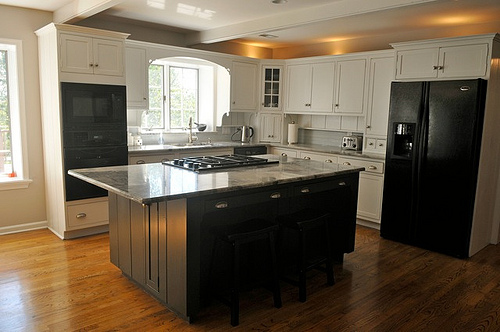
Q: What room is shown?
A: It is a kitchen.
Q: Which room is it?
A: It is a kitchen.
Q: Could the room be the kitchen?
A: Yes, it is the kitchen.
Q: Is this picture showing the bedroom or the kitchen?
A: It is showing the kitchen.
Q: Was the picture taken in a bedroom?
A: No, the picture was taken in a kitchen.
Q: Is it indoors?
A: Yes, it is indoors.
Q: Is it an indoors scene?
A: Yes, it is indoors.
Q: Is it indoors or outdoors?
A: It is indoors.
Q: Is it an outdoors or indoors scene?
A: It is indoors.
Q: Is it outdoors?
A: No, it is indoors.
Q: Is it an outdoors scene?
A: No, it is indoors.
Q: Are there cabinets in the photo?
A: Yes, there is a cabinet.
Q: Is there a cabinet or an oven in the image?
A: Yes, there is a cabinet.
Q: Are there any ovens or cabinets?
A: Yes, there is a cabinet.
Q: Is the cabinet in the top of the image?
A: Yes, the cabinet is in the top of the image.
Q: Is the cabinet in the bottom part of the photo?
A: No, the cabinet is in the top of the image.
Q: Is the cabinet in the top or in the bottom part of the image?
A: The cabinet is in the top of the image.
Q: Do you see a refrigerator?
A: Yes, there is a refrigerator.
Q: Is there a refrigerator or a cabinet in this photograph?
A: Yes, there is a refrigerator.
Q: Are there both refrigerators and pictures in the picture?
A: No, there is a refrigerator but no pictures.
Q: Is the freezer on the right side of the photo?
A: Yes, the freezer is on the right of the image.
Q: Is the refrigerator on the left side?
A: No, the refrigerator is on the right of the image.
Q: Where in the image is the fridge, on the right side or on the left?
A: The fridge is on the right of the image.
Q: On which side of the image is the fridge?
A: The fridge is on the right of the image.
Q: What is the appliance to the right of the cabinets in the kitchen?
A: The appliance is a refrigerator.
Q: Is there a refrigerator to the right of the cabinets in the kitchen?
A: Yes, there is a refrigerator to the right of the cabinets.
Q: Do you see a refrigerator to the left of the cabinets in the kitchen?
A: No, the refrigerator is to the right of the cabinets.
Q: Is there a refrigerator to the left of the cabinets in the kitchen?
A: No, the refrigerator is to the right of the cabinets.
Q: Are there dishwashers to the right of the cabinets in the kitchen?
A: No, there is a refrigerator to the right of the cabinets.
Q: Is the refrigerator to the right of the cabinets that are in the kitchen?
A: Yes, the refrigerator is to the right of the cabinets.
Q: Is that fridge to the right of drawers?
A: No, the fridge is to the right of the cabinets.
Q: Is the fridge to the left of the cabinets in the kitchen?
A: No, the fridge is to the right of the cabinets.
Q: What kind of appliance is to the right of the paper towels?
A: The appliance is a refrigerator.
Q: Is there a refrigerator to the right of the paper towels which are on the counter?
A: Yes, there is a refrigerator to the right of the paper towels.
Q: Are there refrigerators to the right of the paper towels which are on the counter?
A: Yes, there is a refrigerator to the right of the paper towels.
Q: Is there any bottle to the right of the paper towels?
A: No, there is a refrigerator to the right of the paper towels.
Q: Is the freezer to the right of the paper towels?
A: Yes, the freezer is to the right of the paper towels.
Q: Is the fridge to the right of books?
A: No, the fridge is to the right of the paper towels.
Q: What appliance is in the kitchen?
A: The appliance is a refrigerator.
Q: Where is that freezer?
A: The freezer is in the kitchen.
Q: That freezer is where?
A: The freezer is in the kitchen.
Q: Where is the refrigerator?
A: The freezer is in the kitchen.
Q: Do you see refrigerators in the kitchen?
A: Yes, there is a refrigerator in the kitchen.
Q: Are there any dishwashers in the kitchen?
A: No, there is a refrigerator in the kitchen.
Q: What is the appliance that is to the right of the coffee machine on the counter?
A: The appliance is a refrigerator.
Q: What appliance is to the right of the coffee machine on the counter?
A: The appliance is a refrigerator.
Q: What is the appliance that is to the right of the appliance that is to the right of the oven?
A: The appliance is a refrigerator.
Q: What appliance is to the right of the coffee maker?
A: The appliance is a refrigerator.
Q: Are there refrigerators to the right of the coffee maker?
A: Yes, there is a refrigerator to the right of the coffee maker.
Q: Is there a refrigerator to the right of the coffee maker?
A: Yes, there is a refrigerator to the right of the coffee maker.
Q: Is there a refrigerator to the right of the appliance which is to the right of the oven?
A: Yes, there is a refrigerator to the right of the coffee maker.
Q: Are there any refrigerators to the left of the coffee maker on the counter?
A: No, the refrigerator is to the right of the coffee machine.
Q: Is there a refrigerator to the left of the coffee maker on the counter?
A: No, the refrigerator is to the right of the coffee machine.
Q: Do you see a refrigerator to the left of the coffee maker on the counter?
A: No, the refrigerator is to the right of the coffee machine.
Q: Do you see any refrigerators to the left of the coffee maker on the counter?
A: No, the refrigerator is to the right of the coffee machine.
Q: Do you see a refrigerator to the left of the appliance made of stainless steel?
A: No, the refrigerator is to the right of the coffee machine.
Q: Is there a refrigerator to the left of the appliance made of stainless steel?
A: No, the refrigerator is to the right of the coffee machine.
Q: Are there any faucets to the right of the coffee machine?
A: No, there is a refrigerator to the right of the coffee machine.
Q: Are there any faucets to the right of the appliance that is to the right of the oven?
A: No, there is a refrigerator to the right of the coffee machine.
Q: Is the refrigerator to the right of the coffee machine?
A: Yes, the refrigerator is to the right of the coffee machine.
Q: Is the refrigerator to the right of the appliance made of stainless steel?
A: Yes, the refrigerator is to the right of the coffee machine.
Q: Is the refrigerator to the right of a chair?
A: No, the refrigerator is to the right of the coffee machine.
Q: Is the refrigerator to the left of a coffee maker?
A: No, the refrigerator is to the right of a coffee maker.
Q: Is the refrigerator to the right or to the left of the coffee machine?
A: The refrigerator is to the right of the coffee machine.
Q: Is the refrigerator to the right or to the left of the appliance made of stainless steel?
A: The refrigerator is to the right of the coffee machine.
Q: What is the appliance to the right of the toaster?
A: The appliance is a refrigerator.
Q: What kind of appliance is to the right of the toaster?
A: The appliance is a refrigerator.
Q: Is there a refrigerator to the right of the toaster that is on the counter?
A: Yes, there is a refrigerator to the right of the toaster.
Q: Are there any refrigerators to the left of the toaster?
A: No, the refrigerator is to the right of the toaster.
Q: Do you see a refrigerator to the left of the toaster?
A: No, the refrigerator is to the right of the toaster.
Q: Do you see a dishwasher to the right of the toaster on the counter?
A: No, there is a refrigerator to the right of the toaster.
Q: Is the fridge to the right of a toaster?
A: Yes, the fridge is to the right of a toaster.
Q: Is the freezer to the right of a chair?
A: No, the freezer is to the right of a toaster.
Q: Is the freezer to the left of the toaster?
A: No, the freezer is to the right of the toaster.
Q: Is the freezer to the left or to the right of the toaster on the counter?
A: The freezer is to the right of the toaster.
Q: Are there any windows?
A: Yes, there is a window.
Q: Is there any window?
A: Yes, there is a window.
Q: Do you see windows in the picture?
A: Yes, there is a window.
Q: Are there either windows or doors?
A: Yes, there is a window.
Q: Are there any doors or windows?
A: Yes, there is a window.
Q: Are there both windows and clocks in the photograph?
A: No, there is a window but no clocks.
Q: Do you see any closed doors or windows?
A: Yes, there is a closed window.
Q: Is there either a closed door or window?
A: Yes, there is a closed window.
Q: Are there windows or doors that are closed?
A: Yes, the window is closed.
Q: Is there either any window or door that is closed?
A: Yes, the window is closed.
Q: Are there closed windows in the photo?
A: Yes, there is a closed window.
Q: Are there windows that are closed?
A: Yes, there is a window that is closed.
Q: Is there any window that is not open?
A: Yes, there is an closed window.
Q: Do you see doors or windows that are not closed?
A: No, there is a window but it is closed.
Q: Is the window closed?
A: Yes, the window is closed.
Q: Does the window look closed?
A: Yes, the window is closed.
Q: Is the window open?
A: No, the window is closed.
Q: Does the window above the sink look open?
A: No, the window is closed.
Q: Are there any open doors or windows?
A: No, there is a window but it is closed.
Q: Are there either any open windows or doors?
A: No, there is a window but it is closed.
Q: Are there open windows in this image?
A: No, there is a window but it is closed.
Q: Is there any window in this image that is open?
A: No, there is a window but it is closed.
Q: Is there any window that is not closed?
A: No, there is a window but it is closed.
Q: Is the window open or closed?
A: The window is closed.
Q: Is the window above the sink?
A: Yes, the window is above the sink.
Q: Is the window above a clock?
A: No, the window is above the sink.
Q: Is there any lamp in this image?
A: No, there are no lamps.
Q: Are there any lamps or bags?
A: No, there are no lamps or bags.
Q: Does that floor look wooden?
A: Yes, the floor is wooden.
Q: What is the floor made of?
A: The floor is made of wood.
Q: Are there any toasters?
A: Yes, there is a toaster.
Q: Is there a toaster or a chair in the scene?
A: Yes, there is a toaster.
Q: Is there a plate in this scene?
A: No, there are no plates.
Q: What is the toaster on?
A: The toaster is on the counter.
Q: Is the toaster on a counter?
A: Yes, the toaster is on a counter.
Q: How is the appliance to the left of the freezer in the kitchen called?
A: The appliance is a toaster.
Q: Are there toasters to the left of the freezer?
A: Yes, there is a toaster to the left of the freezer.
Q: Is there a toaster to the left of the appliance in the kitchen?
A: Yes, there is a toaster to the left of the freezer.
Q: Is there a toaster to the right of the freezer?
A: No, the toaster is to the left of the freezer.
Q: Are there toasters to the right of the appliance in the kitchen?
A: No, the toaster is to the left of the freezer.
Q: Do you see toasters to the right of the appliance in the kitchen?
A: No, the toaster is to the left of the freezer.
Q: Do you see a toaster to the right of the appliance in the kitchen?
A: No, the toaster is to the left of the freezer.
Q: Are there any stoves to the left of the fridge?
A: No, there is a toaster to the left of the fridge.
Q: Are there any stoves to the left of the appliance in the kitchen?
A: No, there is a toaster to the left of the fridge.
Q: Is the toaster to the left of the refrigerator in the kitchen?
A: Yes, the toaster is to the left of the fridge.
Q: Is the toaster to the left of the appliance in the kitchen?
A: Yes, the toaster is to the left of the fridge.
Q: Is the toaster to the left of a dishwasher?
A: No, the toaster is to the left of the fridge.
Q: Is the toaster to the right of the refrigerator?
A: No, the toaster is to the left of the refrigerator.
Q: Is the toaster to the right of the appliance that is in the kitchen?
A: No, the toaster is to the left of the refrigerator.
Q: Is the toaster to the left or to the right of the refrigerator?
A: The toaster is to the left of the refrigerator.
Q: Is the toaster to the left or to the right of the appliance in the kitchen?
A: The toaster is to the left of the refrigerator.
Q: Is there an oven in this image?
A: Yes, there is an oven.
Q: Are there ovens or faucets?
A: Yes, there is an oven.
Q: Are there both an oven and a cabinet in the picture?
A: Yes, there are both an oven and a cabinet.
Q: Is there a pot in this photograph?
A: No, there are no pots.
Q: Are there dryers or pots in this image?
A: No, there are no pots or dryers.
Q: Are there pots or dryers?
A: No, there are no pots or dryers.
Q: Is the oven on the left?
A: Yes, the oven is on the left of the image.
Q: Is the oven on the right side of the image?
A: No, the oven is on the left of the image.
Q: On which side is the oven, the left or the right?
A: The oven is on the left of the image.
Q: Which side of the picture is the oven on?
A: The oven is on the left of the image.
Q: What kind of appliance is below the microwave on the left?
A: The appliance is an oven.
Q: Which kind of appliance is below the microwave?
A: The appliance is an oven.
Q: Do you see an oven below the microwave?
A: Yes, there is an oven below the microwave.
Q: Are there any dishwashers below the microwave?
A: No, there is an oven below the microwave.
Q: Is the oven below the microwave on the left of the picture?
A: Yes, the oven is below the microwave.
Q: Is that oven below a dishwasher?
A: No, the oven is below the microwave.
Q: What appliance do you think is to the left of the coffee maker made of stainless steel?
A: The appliance is an oven.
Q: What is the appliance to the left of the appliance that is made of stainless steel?
A: The appliance is an oven.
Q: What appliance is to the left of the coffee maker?
A: The appliance is an oven.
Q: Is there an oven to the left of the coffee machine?
A: Yes, there is an oven to the left of the coffee machine.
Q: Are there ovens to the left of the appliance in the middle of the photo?
A: Yes, there is an oven to the left of the coffee machine.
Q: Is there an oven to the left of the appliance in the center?
A: Yes, there is an oven to the left of the coffee machine.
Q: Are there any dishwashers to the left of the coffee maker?
A: No, there is an oven to the left of the coffee maker.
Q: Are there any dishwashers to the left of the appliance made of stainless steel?
A: No, there is an oven to the left of the coffee maker.